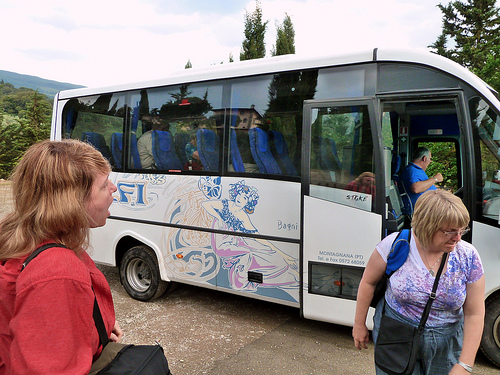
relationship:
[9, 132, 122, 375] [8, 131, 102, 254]
person has hair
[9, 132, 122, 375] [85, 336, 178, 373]
person has bag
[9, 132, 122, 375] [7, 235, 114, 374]
person has shirt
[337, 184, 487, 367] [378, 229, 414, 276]
woman has strap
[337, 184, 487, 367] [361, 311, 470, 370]
woman has pants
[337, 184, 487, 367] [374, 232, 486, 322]
woman has shirt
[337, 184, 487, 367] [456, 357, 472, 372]
woman has band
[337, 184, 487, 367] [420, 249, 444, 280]
woman has necklace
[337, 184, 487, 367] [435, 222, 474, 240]
woman has glasses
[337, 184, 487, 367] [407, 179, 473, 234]
woman has hair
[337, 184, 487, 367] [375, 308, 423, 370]
woman has bag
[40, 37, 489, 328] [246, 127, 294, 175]
bus has seats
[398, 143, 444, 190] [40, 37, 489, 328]
driver on bus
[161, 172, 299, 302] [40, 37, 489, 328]
advertisement on bus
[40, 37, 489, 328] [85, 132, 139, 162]
bus has seats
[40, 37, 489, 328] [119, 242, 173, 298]
bus has tire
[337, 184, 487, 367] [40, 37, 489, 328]
woman near bus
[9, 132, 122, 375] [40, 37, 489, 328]
person near bus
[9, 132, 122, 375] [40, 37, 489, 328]
person looking at bus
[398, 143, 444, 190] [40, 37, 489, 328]
driver driving bus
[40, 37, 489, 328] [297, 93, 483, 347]
bus has door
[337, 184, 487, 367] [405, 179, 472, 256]
woman has head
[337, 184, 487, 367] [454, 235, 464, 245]
woman has nose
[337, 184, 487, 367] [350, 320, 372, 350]
woman has hand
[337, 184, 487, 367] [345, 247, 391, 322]
woman has arm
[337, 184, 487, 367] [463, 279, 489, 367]
woman has arm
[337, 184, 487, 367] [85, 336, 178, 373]
woman has bag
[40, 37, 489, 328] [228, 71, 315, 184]
bus has window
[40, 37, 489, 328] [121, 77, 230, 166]
bus has window